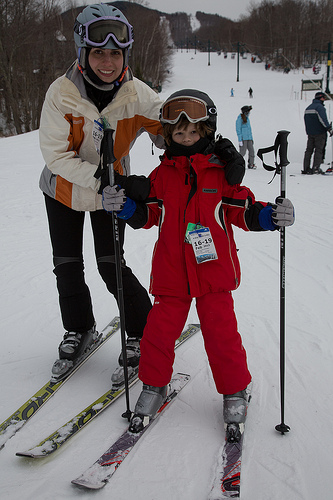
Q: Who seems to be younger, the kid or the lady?
A: The kid is younger than the lady.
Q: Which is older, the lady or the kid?
A: The lady is older than the kid.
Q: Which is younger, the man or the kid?
A: The kid is younger than the man.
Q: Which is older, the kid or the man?
A: The man is older than the kid.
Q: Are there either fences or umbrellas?
A: No, there are no umbrellas or fences.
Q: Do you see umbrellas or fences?
A: No, there are no umbrellas or fences.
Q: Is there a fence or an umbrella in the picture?
A: No, there are no umbrellas or fences.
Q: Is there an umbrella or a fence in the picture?
A: No, there are no umbrellas or fences.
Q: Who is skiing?
A: The people are skiing.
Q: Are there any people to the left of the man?
A: Yes, there are people to the left of the man.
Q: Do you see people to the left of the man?
A: Yes, there are people to the left of the man.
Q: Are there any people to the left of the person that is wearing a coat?
A: Yes, there are people to the left of the man.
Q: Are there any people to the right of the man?
A: No, the people are to the left of the man.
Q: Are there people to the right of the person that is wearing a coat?
A: No, the people are to the left of the man.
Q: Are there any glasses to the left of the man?
A: No, there are people to the left of the man.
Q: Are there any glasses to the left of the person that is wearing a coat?
A: No, there are people to the left of the man.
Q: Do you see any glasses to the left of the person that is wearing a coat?
A: No, there are people to the left of the man.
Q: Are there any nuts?
A: No, there are no nuts.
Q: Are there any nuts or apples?
A: No, there are no nuts or apples.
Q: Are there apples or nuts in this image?
A: No, there are no nuts or apples.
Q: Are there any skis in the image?
A: Yes, there are skis.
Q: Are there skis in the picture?
A: Yes, there are skis.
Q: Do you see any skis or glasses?
A: Yes, there are skis.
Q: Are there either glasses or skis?
A: Yes, there are skis.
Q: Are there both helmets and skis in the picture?
A: Yes, there are both skis and a helmet.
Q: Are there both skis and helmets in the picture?
A: Yes, there are both skis and a helmet.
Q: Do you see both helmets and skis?
A: Yes, there are both skis and a helmet.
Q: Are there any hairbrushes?
A: No, there are no hairbrushes.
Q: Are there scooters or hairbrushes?
A: No, there are no hairbrushes or scooters.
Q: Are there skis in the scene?
A: Yes, there are skis.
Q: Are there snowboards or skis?
A: Yes, there are skis.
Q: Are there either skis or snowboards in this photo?
A: Yes, there are skis.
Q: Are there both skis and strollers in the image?
A: No, there are skis but no strollers.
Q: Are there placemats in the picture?
A: No, there are no placemats.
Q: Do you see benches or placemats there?
A: No, there are no placemats or benches.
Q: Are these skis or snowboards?
A: These are skis.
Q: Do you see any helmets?
A: Yes, there is a helmet.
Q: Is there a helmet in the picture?
A: Yes, there is a helmet.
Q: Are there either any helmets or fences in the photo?
A: Yes, there is a helmet.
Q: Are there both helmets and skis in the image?
A: Yes, there are both a helmet and skis.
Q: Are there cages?
A: No, there are no cages.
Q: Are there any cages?
A: No, there are no cages.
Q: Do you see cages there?
A: No, there are no cages.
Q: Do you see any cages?
A: No, there are no cages.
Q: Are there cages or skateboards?
A: No, there are no cages or skateboards.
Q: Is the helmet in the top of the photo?
A: Yes, the helmet is in the top of the image.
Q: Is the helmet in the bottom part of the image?
A: No, the helmet is in the top of the image.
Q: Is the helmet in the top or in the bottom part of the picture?
A: The helmet is in the top of the image.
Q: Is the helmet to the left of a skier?
A: Yes, the helmet is to the left of a skier.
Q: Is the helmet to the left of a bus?
A: No, the helmet is to the left of a skier.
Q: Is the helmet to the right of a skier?
A: No, the helmet is to the left of a skier.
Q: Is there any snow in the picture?
A: Yes, there is snow.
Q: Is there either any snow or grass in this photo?
A: Yes, there is snow.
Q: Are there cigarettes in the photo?
A: No, there are no cigarettes.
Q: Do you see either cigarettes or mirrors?
A: No, there are no cigarettes or mirrors.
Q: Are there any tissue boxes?
A: No, there are no tissue boxes.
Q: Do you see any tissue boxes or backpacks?
A: No, there are no tissue boxes or backpacks.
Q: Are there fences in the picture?
A: No, there are no fences.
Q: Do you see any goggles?
A: Yes, there are goggles.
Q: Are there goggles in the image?
A: Yes, there are goggles.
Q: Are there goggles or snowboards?
A: Yes, there are goggles.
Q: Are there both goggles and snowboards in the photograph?
A: No, there are goggles but no snowboards.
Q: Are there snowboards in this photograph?
A: No, there are no snowboards.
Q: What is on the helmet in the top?
A: The goggles are on the helmet.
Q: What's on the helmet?
A: The goggles are on the helmet.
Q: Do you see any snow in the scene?
A: Yes, there is snow.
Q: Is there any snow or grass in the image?
A: Yes, there is snow.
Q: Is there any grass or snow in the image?
A: Yes, there is snow.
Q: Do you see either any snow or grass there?
A: Yes, there is snow.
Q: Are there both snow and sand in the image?
A: No, there is snow but no sand.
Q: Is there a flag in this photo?
A: No, there are no flags.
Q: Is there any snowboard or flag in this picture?
A: No, there are no flags or snowboards.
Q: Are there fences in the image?
A: No, there are no fences.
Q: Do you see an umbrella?
A: No, there are no umbrellas.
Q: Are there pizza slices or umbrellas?
A: No, there are no umbrellas or pizza slices.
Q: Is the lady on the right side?
A: Yes, the lady is on the right of the image.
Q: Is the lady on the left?
A: No, the lady is on the right of the image.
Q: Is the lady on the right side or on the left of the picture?
A: The lady is on the right of the image.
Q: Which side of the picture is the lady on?
A: The lady is on the right of the image.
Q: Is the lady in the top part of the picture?
A: Yes, the lady is in the top of the image.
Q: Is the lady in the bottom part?
A: No, the lady is in the top of the image.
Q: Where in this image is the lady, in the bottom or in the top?
A: The lady is in the top of the image.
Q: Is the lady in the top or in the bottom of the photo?
A: The lady is in the top of the image.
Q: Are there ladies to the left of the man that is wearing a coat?
A: Yes, there is a lady to the left of the man.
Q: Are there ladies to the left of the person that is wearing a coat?
A: Yes, there is a lady to the left of the man.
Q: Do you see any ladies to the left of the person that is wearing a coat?
A: Yes, there is a lady to the left of the man.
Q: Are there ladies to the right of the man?
A: No, the lady is to the left of the man.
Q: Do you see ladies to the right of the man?
A: No, the lady is to the left of the man.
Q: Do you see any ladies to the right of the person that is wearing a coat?
A: No, the lady is to the left of the man.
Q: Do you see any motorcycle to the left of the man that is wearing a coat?
A: No, there is a lady to the left of the man.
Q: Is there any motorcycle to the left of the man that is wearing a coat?
A: No, there is a lady to the left of the man.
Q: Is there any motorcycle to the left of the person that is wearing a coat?
A: No, there is a lady to the left of the man.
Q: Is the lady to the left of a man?
A: Yes, the lady is to the left of a man.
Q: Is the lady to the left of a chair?
A: No, the lady is to the left of a man.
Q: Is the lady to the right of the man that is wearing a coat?
A: No, the lady is to the left of the man.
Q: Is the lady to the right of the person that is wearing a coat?
A: No, the lady is to the left of the man.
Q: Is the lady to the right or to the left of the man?
A: The lady is to the left of the man.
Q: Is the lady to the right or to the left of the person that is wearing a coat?
A: The lady is to the left of the man.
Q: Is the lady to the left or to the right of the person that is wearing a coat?
A: The lady is to the left of the man.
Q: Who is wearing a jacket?
A: The lady is wearing a jacket.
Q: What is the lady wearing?
A: The lady is wearing a jacket.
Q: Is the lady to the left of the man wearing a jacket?
A: Yes, the lady is wearing a jacket.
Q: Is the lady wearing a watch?
A: No, the lady is wearing a jacket.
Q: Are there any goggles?
A: Yes, there are goggles.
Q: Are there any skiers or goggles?
A: Yes, there are goggles.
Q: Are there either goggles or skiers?
A: Yes, there are goggles.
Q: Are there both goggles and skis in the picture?
A: Yes, there are both goggles and skis.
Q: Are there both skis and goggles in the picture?
A: Yes, there are both goggles and skis.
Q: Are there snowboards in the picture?
A: No, there are no snowboards.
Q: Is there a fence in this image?
A: No, there are no fences.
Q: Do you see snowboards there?
A: No, there are no snowboards.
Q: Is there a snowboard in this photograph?
A: No, there are no snowboards.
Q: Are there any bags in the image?
A: No, there are no bags.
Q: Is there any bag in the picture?
A: No, there are no bags.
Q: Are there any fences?
A: No, there are no fences.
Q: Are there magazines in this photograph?
A: No, there are no magazines.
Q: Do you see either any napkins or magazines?
A: No, there are no magazines or napkins.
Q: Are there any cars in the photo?
A: No, there are no cars.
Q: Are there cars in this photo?
A: No, there are no cars.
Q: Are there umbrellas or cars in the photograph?
A: No, there are no cars or umbrellas.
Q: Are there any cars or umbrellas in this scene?
A: No, there are no cars or umbrellas.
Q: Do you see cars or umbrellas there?
A: No, there are no cars or umbrellas.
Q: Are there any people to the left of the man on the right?
A: Yes, there are people to the left of the man.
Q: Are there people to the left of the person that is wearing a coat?
A: Yes, there are people to the left of the man.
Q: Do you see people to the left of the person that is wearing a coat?
A: Yes, there are people to the left of the man.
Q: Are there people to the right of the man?
A: No, the people are to the left of the man.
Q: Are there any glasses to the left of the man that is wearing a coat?
A: No, there are people to the left of the man.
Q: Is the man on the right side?
A: Yes, the man is on the right of the image.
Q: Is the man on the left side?
A: No, the man is on the right of the image.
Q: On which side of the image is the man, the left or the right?
A: The man is on the right of the image.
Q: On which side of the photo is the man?
A: The man is on the right of the image.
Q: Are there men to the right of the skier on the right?
A: Yes, there is a man to the right of the skier.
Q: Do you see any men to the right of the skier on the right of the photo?
A: Yes, there is a man to the right of the skier.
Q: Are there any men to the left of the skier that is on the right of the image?
A: No, the man is to the right of the skier.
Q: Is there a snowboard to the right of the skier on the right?
A: No, there is a man to the right of the skier.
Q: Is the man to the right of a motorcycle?
A: No, the man is to the right of a skier.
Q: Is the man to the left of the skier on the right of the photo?
A: No, the man is to the right of the skier.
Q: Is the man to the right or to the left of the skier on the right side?
A: The man is to the right of the skier.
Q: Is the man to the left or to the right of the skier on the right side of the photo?
A: The man is to the right of the skier.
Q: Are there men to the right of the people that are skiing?
A: Yes, there is a man to the right of the people.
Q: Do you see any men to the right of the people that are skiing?
A: Yes, there is a man to the right of the people.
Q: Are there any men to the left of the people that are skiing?
A: No, the man is to the right of the people.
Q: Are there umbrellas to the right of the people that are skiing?
A: No, there is a man to the right of the people.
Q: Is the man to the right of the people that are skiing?
A: Yes, the man is to the right of the people.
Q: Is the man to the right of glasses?
A: No, the man is to the right of the people.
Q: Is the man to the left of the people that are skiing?
A: No, the man is to the right of the people.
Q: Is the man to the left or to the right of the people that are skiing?
A: The man is to the right of the people.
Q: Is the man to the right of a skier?
A: Yes, the man is to the right of a skier.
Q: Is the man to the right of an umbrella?
A: No, the man is to the right of a skier.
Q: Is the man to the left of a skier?
A: No, the man is to the right of a skier.